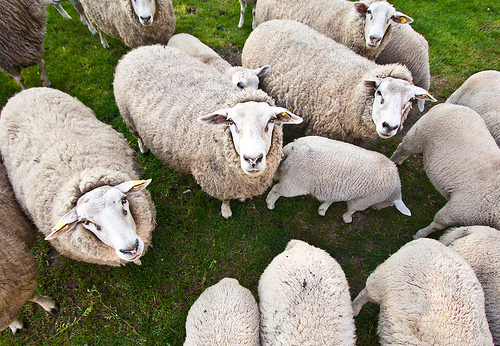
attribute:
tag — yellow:
[219, 110, 232, 120]